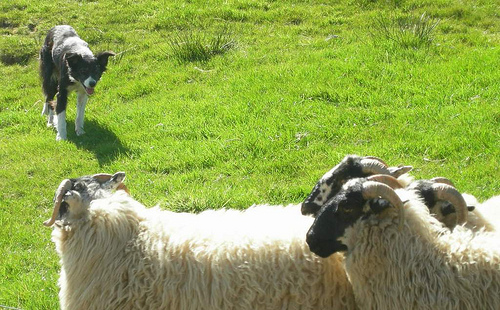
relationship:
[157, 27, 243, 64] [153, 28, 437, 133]
grass in grass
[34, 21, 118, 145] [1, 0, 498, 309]
dog standing on grass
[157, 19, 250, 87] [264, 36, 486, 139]
grass stands out field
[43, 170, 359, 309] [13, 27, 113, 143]
sheep near dog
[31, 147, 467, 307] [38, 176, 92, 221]
sheep with horns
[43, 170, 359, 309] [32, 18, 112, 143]
sheep watching dog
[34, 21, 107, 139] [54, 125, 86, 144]
dog with paws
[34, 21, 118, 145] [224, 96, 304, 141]
dog has paws in grass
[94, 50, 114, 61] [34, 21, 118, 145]
black ear of dog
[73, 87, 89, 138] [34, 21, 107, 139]
leg on a dog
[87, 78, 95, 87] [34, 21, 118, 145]
nose of a dog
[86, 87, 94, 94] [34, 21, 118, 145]
tongue of a dog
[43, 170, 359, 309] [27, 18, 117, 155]
sheep herded by dog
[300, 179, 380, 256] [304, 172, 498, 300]
face of a sheep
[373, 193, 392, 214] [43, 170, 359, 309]
horn of a sheep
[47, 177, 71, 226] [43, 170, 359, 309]
horn of a sheep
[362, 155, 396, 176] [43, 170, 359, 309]
horn of a sheep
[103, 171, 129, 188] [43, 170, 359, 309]
ear of a sheep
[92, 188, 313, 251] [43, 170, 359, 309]
sunlight on sheep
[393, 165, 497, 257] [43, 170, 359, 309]
sunlight on sheep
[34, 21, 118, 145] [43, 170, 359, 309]
dog watching sheep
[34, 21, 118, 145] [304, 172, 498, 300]
dog watching sheep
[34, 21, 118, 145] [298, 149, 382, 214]
dog watching sheep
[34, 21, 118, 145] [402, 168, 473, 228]
dog watching sheep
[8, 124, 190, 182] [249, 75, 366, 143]
dog's shadow on grass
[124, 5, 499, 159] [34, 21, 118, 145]
grass and dog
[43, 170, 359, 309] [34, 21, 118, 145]
sheep and dog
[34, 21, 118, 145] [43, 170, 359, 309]
dog and sheep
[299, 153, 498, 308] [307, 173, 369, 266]
two sheep with faces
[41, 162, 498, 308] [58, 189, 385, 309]
fur on sheep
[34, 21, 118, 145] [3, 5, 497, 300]
dog standing in field